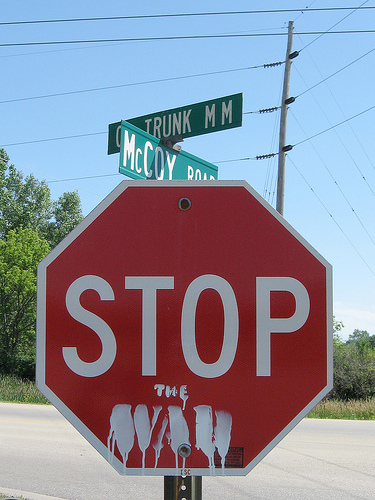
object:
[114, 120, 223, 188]
sign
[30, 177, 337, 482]
stop sign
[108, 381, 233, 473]
graffiti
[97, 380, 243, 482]
post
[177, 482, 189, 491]
hole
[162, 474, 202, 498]
pole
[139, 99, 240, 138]
lettering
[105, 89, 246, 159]
sign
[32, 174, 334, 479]
outer edge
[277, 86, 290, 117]
pole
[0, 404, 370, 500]
road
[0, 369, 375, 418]
grass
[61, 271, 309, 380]
lettering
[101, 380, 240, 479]
wording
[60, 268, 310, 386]
stop